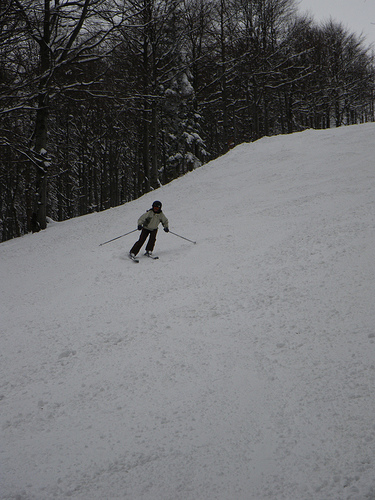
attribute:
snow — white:
[2, 116, 374, 500]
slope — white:
[2, 118, 374, 263]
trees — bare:
[3, 2, 369, 244]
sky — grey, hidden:
[3, 3, 373, 54]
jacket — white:
[138, 212, 170, 232]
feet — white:
[127, 251, 158, 259]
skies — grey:
[128, 251, 160, 264]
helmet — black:
[153, 199, 162, 202]